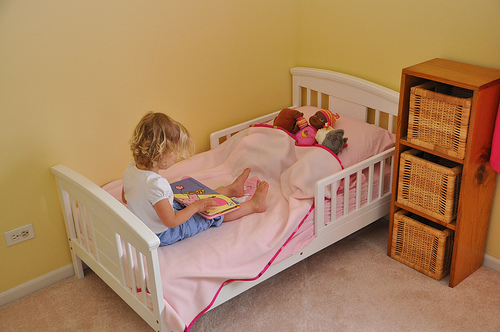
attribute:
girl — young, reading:
[120, 111, 270, 247]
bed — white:
[50, 65, 399, 331]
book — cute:
[167, 177, 239, 219]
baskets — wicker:
[387, 81, 471, 278]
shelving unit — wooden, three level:
[385, 57, 499, 288]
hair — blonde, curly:
[128, 111, 194, 170]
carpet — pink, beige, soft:
[0, 215, 498, 330]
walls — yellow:
[1, 0, 499, 294]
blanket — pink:
[75, 123, 345, 330]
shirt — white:
[121, 163, 175, 233]